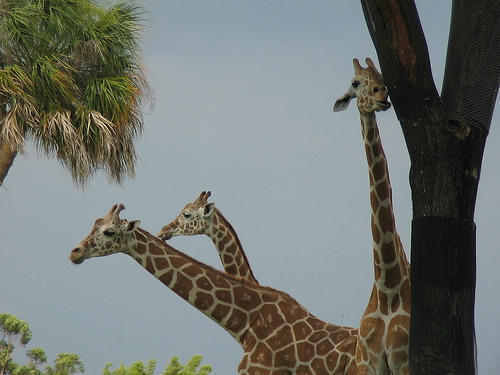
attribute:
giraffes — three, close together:
[338, 38, 413, 372]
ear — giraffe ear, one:
[331, 86, 353, 116]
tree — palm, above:
[4, 3, 140, 198]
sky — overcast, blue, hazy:
[0, 0, 500, 375]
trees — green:
[0, 1, 498, 372]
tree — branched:
[354, 0, 495, 375]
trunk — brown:
[387, 128, 492, 374]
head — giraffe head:
[53, 199, 153, 273]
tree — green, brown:
[0, 32, 158, 201]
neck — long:
[210, 222, 261, 283]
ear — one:
[313, 90, 373, 127]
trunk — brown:
[359, 0, 499, 373]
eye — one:
[348, 78, 363, 90]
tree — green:
[6, 7, 147, 172]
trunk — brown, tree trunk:
[401, 114, 486, 367]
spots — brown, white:
[136, 235, 408, 356]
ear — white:
[110, 200, 127, 212]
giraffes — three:
[52, 48, 419, 373]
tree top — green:
[1, 0, 153, 193]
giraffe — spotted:
[69, 202, 364, 373]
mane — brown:
[137, 225, 287, 295]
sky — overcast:
[167, 23, 305, 170]